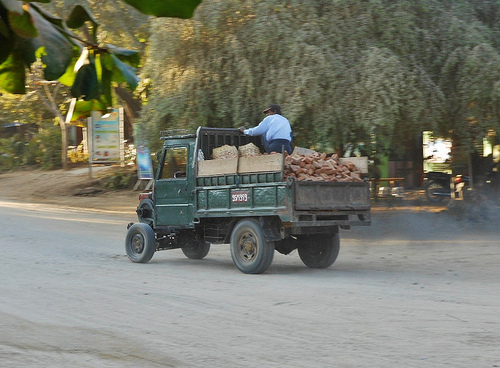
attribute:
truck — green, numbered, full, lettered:
[122, 121, 376, 273]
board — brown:
[193, 152, 284, 174]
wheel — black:
[228, 218, 274, 274]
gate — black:
[291, 176, 374, 210]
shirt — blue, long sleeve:
[243, 111, 293, 142]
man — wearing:
[241, 105, 294, 155]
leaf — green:
[106, 48, 139, 94]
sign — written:
[85, 115, 125, 163]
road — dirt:
[2, 208, 499, 367]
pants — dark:
[260, 136, 296, 153]